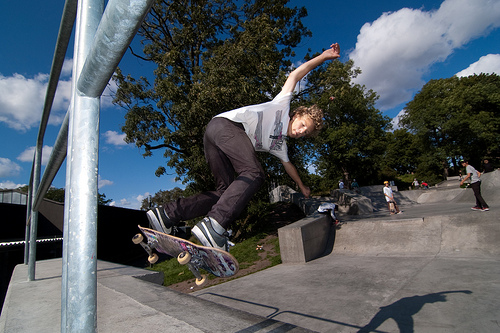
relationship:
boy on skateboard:
[145, 41, 339, 251] [134, 224, 238, 287]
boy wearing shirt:
[145, 41, 339, 251] [213, 94, 290, 162]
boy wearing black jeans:
[145, 41, 339, 251] [162, 117, 264, 227]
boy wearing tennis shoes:
[145, 41, 339, 251] [146, 204, 231, 255]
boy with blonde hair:
[145, 41, 339, 251] [293, 103, 323, 131]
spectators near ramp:
[338, 178, 360, 188] [335, 185, 400, 216]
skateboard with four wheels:
[134, 224, 238, 287] [133, 232, 205, 285]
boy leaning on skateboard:
[383, 180, 402, 213] [387, 200, 397, 215]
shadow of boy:
[358, 290, 471, 332] [145, 41, 339, 251]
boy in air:
[145, 41, 339, 251] [1, 1, 499, 332]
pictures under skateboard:
[180, 241, 234, 279] [134, 224, 238, 287]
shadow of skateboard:
[358, 290, 471, 332] [134, 224, 238, 287]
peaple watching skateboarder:
[337, 156, 488, 213] [145, 41, 339, 251]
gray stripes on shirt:
[255, 110, 282, 150] [213, 94, 290, 162]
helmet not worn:
[292, 101, 336, 144] [294, 102, 323, 134]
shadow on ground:
[358, 290, 471, 332] [0, 185, 496, 331]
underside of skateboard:
[137, 226, 234, 286] [134, 224, 238, 287]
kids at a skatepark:
[150, 42, 487, 241] [0, 190, 499, 330]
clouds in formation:
[337, 2, 499, 110] [338, 3, 498, 101]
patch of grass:
[151, 234, 260, 280] [145, 242, 260, 284]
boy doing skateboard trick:
[145, 41, 339, 251] [132, 42, 340, 288]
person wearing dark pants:
[459, 152, 489, 210] [469, 182, 486, 208]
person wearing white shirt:
[459, 152, 489, 210] [464, 166, 480, 183]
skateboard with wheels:
[134, 224, 238, 287] [133, 232, 205, 285]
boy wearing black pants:
[145, 41, 339, 251] [162, 117, 264, 227]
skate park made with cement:
[0, 190, 499, 330] [3, 171, 499, 333]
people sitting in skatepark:
[406, 178, 430, 190] [0, 190, 499, 330]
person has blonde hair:
[145, 41, 339, 251] [293, 103, 323, 131]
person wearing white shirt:
[145, 41, 339, 251] [213, 94, 290, 162]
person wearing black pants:
[459, 152, 489, 210] [469, 182, 486, 208]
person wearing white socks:
[145, 41, 339, 251] [209, 216, 227, 235]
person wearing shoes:
[145, 41, 339, 251] [146, 204, 231, 255]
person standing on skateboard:
[383, 180, 402, 213] [387, 200, 397, 215]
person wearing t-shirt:
[145, 41, 339, 251] [213, 94, 290, 162]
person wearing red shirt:
[420, 179, 429, 191] [423, 182, 427, 186]